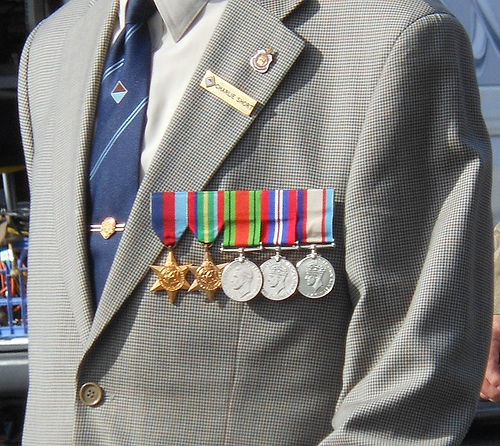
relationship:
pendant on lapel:
[150, 182, 191, 314] [134, 7, 310, 289]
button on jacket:
[76, 385, 110, 410] [29, 3, 437, 445]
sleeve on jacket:
[330, 33, 468, 446] [29, 3, 437, 445]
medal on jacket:
[142, 194, 334, 300] [29, 3, 437, 445]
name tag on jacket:
[182, 64, 278, 129] [29, 3, 437, 445]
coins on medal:
[209, 250, 349, 302] [142, 194, 334, 300]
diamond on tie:
[102, 87, 146, 110] [72, 7, 155, 295]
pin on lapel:
[243, 45, 282, 66] [134, 7, 310, 289]